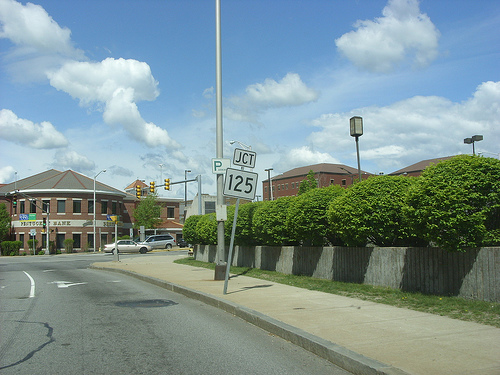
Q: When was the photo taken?
A: Day time.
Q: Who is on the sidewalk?
A: Unoccupied.